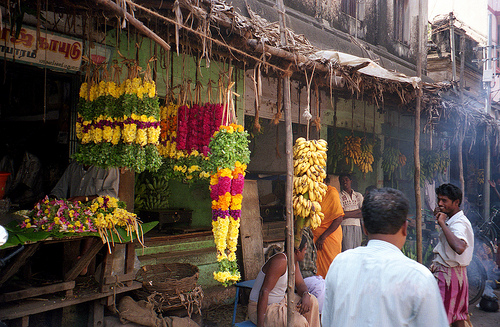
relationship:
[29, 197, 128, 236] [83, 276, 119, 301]
food on counter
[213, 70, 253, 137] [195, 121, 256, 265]
rope holding food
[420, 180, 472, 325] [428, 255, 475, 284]
man wearing shirt around waist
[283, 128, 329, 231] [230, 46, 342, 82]
banana hang from a roof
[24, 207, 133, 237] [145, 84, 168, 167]
bouquet of flower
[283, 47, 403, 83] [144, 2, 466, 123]
awning of roof